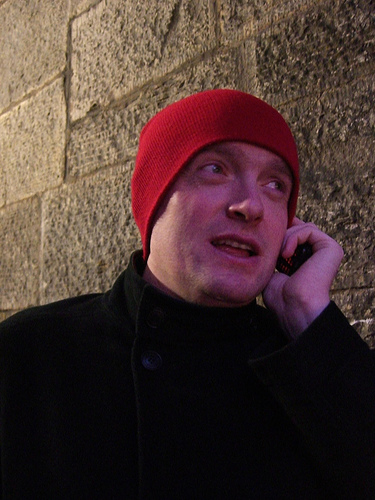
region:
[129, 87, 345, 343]
a man talking on a cellphone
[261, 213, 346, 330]
a hand holding a cellphone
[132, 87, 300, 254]
a red beanie on a man's head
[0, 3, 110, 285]
a brick wall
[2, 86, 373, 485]
a man wearing a black coat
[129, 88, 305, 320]
a man wearing a red hat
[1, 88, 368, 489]
a man looking amused while talking on the phone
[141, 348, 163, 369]
a black button on a black coat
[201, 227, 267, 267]
an open mouth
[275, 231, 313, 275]
a cellphone in use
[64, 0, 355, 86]
Brown brick wall behind the man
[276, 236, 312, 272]
Cell phone the guy is talking on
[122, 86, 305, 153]
Man is wearing a red winter hat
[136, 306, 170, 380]
Black buttons at the top of the coat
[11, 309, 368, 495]
Man wears a thick black coat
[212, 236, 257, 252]
The top row of his teeth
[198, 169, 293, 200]
Puffy bags under both of man's eyes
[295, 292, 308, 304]
A bony prominence on man's left wrist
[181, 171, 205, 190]
The gentleman has crow's feet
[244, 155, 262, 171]
Un-tweezed hairs in between his eyebrows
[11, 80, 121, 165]
group of stones for wall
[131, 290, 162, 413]
two jacket buttons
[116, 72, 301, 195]
warm red winter hat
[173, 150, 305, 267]
male facial features smiling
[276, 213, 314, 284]
hand held cell phone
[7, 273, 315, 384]
mans black winter jacket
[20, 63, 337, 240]
man standing by stone wall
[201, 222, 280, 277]
man talking n cell phone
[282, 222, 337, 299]
mans hand holding cell phone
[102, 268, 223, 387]
button up winter jacket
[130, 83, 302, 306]
Man wearing a red beanie hat.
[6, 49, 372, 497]
Man standing next to a wall.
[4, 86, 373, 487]
Man dressed in a black jacket.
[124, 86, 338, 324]
Man talking on cell phone.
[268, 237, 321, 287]
Man using black colored cell phone.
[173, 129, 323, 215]
Man looking away from photographer.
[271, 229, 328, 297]
Man using black cell phone that has orange buttons.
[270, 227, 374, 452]
man holding cell phone in his left hand.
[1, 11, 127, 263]
A wall made out of stones.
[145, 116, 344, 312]
The man on his cell phone is intensely involved in his conversation.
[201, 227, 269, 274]
a man talking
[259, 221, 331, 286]
Man holding cell phone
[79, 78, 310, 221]
a man's winter cap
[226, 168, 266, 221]
A man's nose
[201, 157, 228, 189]
A man's eyeball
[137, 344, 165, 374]
Button on a jacket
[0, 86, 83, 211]
brick on a building behind the man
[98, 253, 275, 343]
Collar on a jacket of the man.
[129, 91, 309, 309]
A caucasian male's face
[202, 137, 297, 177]
A man's eyebrows at rest.